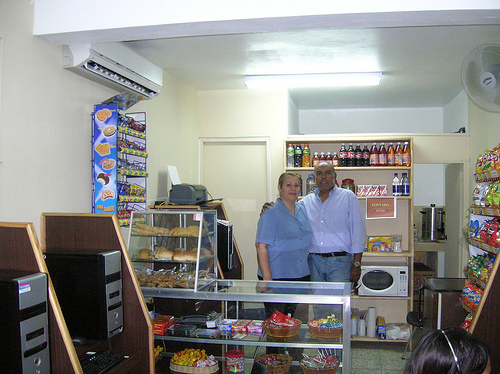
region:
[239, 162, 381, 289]
The man and the woman in the store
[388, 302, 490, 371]
A person has on headphones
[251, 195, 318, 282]
The woman has on a blue shirt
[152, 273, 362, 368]
The glass counter in the store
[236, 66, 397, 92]
The light on the ceiling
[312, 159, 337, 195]
The head of the man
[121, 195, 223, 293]
The bread storage container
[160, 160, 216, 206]
The printer on the shelf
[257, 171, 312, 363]
woman standing wearing light blue t-shirt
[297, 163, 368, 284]
man standing wearing light blue t-shirt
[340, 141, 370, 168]
coca-cola bottles on the counter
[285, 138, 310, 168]
Gatorade bottles on the counter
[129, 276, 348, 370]
counter where cadies are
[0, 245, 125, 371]
two black and grays case of computer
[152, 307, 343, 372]
candies on a counter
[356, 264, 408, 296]
white microwave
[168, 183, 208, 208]
gray printer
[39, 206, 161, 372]
a tall wall divider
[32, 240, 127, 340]
part of a computer cpu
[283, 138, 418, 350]
a large brown shelf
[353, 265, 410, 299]
a small microwave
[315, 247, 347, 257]
part of a man's black belt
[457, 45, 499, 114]
part of a large white fan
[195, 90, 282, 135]
part of a painted wall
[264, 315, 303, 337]
a brown basket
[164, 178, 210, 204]
a gray printer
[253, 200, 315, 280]
a woman's blue shirt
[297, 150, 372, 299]
Mn wearing a blue shirt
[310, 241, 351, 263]
Belt around the man's waist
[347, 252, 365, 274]
Watch on the man's wrist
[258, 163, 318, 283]
Woman wearing a blue shirt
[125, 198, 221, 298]
Display case on counter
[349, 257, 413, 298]
Microwave in the background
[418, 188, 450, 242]
Coffee pot in the background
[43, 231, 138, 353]
Computer modem on desk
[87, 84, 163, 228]
Shelf against the wall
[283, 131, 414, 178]
Bottles on top shelf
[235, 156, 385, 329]
man and lady standing in cafe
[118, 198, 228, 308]
pastry oven with pastries in it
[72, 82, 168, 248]
cookie rack on wall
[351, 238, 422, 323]
white microwave on shelf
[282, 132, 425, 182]
soda drinks on shelf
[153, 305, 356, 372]
candy bowls in glass cabinet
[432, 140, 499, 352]
chips on shelves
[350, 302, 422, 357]
cups stacked on shelf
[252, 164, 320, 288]
lady wearing blue shirt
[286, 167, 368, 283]
man wearing blue shirt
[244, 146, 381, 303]
man and woman standing together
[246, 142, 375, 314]
man and woman standing together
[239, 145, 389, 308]
man and woman standing together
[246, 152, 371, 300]
man and woman standing together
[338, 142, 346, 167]
a 2 liter bottle of soda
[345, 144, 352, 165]
a 2 liter bottle of soda